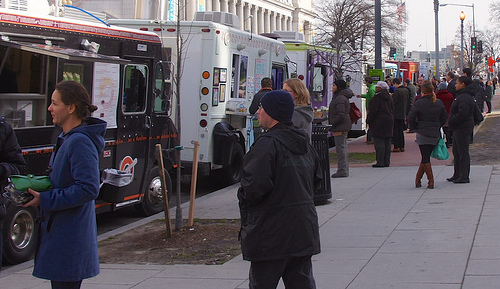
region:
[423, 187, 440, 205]
small spot on side walk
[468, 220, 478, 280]
lines in side walk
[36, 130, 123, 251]
woman wearing blue coat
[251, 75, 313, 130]
blue cap on man's head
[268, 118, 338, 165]
black hoodie on jacket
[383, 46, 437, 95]
orange food truck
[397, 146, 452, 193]
woman wearing brown boots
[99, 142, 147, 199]
orange and white logo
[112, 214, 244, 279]
brown dirt on the side walk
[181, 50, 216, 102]
red light on the white food truck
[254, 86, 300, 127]
hat on a persons head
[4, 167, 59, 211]
green purse in a persons hands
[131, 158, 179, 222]
front wheel of a vehicle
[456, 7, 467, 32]
street light on a pole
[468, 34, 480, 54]
traffic signal on a pole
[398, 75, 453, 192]
person with a green bag standing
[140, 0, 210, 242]
tree without leave on a sidewalk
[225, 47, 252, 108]
side window on a vehicle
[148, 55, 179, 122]
side rear view mirror on a vehicle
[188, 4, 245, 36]
air conditioning unit on a vehicle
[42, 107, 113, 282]
The blue coat worn by the lady.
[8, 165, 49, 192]
The green purse in the lady's hand that is wearing the blue coat.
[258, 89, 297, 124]
The blue hat the man in the black jacket is wearing.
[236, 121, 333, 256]
The black hooded jacket the man in the blue hat is wearing.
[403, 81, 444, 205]
The lady standing on the sidewalk in brown boots.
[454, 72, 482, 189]
The lady in all black standing next to the lady in brown boots.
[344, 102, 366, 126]
The brown bag the lady in gray jeans is carrying.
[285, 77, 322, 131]
The lady with blonde hair in the gray coat.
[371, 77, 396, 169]
The lady with a white hand on to the right of the lady holding the brown purse/bag.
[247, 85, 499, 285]
The sidewalk where the group of people are standing.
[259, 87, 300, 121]
a blue knit cap on a man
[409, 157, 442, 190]
brown boots on a woman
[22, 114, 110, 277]
a blue coat on a woman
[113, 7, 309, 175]
a white vendor truck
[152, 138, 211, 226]
two posts suporting a tree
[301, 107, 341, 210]
a green metal trashcan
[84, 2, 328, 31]
a building with columns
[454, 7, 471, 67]
a lamp post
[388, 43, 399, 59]
a green light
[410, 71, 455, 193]
a woman carrying an aqua purse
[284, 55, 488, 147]
people on queue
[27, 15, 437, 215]
food trucks are parked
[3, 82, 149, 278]
the woman is carrying a purse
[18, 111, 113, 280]
the coat is blue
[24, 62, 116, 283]
the woman is wearing a coat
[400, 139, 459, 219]
the boots are brown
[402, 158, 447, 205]
the woman is wearing boots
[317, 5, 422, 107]
the trees are bare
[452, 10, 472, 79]
the lamp post is on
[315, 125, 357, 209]
the trash bin is black